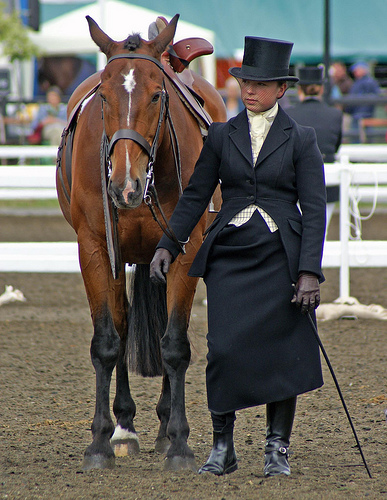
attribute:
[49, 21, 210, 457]
horse — beautiful, brown, healty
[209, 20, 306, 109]
hat — black, tall, fashionablee, large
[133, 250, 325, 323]
gloves — brown, leather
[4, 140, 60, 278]
fence — white, short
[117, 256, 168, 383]
tail — black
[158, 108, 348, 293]
coat — blue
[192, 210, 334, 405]
skirt — blue, brown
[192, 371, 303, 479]
boots — black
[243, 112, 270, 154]
shirt — white